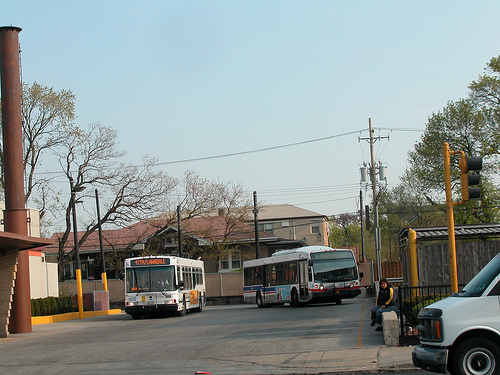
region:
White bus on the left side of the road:
[103, 242, 221, 333]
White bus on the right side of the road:
[225, 241, 395, 318]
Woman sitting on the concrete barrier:
[363, 275, 403, 334]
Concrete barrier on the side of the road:
[365, 271, 407, 351]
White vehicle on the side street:
[398, 221, 498, 371]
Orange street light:
[411, 122, 496, 298]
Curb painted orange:
[24, 303, 136, 329]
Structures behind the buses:
[43, 169, 360, 301]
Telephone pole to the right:
[321, 110, 403, 305]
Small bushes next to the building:
[31, 284, 110, 324]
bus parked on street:
[106, 255, 209, 325]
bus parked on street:
[232, 241, 360, 306]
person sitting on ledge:
[366, 274, 397, 323]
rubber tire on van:
[452, 343, 492, 372]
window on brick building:
[307, 220, 324, 236]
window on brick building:
[231, 257, 242, 271]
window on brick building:
[218, 260, 230, 272]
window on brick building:
[212, 249, 228, 261]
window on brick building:
[228, 250, 242, 260]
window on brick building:
[264, 222, 274, 234]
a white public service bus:
[120, 252, 209, 320]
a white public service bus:
[240, 243, 363, 305]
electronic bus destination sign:
[129, 256, 164, 266]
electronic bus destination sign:
[309, 252, 351, 260]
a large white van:
[415, 245, 498, 372]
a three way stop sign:
[439, 139, 485, 291]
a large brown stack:
[0, 19, 48, 326]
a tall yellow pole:
[69, 265, 89, 322]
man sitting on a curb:
[369, 276, 399, 331]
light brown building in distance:
[239, 200, 327, 245]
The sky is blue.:
[165, 30, 304, 103]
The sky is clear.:
[145, 25, 282, 120]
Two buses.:
[106, 232, 362, 327]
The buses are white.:
[105, 227, 361, 319]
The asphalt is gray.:
[215, 317, 261, 357]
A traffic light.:
[434, 132, 488, 307]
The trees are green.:
[402, 57, 498, 226]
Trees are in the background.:
[393, 50, 497, 200]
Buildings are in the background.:
[46, 178, 349, 309]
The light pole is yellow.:
[424, 137, 490, 300]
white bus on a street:
[123, 253, 209, 317]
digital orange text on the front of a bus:
[130, 256, 172, 266]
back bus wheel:
[255, 291, 266, 306]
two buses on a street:
[123, 246, 366, 317]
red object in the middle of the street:
[188, 367, 215, 374]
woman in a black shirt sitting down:
[370, 274, 402, 331]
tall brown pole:
[2, 21, 34, 333]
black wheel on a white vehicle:
[446, 327, 498, 374]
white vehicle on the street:
[410, 251, 499, 374]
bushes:
[27, 295, 79, 316]